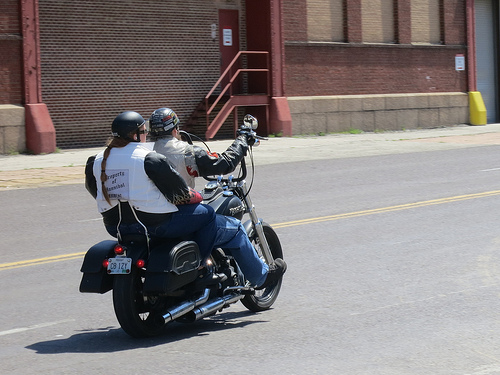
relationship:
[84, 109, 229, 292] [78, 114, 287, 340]
people sitting on top of motorcycle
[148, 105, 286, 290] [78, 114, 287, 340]
man riding motorcycle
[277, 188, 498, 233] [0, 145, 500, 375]
line painted on road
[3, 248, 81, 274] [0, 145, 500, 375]
line painted on road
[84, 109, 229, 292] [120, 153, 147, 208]
people wearing vest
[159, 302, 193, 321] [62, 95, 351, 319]
muffler on motorcycle.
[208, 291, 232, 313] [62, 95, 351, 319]
muffler on motorcycle.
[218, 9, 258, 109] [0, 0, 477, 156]
door on brick building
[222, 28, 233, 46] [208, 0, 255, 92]
sign on door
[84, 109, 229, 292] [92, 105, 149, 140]
people wearing helmet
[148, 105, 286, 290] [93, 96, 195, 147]
man wearing helmet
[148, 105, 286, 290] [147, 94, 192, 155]
man wearing helmet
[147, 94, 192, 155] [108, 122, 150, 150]
helmet on head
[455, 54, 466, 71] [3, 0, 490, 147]
sign on building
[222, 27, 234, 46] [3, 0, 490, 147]
sign on building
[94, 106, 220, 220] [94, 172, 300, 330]
people on motorcycle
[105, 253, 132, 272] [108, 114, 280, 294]
license plate on motorcycle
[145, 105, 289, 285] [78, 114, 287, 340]
man driving motorcycle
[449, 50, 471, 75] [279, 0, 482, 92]
sign on building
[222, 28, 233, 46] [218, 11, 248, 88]
sign on door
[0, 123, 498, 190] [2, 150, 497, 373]
sidewalk next to road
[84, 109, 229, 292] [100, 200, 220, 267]
people wearing jeans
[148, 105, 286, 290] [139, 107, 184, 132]
man wearing helmet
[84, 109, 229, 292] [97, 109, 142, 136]
people wearing helmet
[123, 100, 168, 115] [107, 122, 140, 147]
sun bouncing off helmet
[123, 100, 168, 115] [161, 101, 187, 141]
sun bouncing off helmet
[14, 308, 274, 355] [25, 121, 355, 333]
shadow under motorcycle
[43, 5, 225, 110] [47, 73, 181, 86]
wall with grout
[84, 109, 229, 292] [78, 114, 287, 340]
people on motorcycle